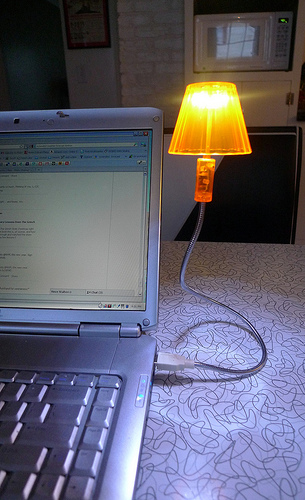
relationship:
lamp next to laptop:
[156, 81, 266, 378] [1, 105, 165, 498]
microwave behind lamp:
[194, 12, 292, 74] [156, 81, 266, 378]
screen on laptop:
[1, 129, 154, 310] [1, 105, 165, 498]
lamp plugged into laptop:
[156, 81, 266, 378] [1, 105, 165, 498]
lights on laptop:
[137, 375, 154, 409] [1, 105, 165, 498]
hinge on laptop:
[77, 322, 122, 340] [1, 105, 165, 498]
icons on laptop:
[2, 131, 153, 310] [1, 105, 165, 498]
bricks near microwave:
[117, 1, 186, 128] [194, 12, 292, 74]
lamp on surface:
[156, 81, 266, 378] [131, 239, 304, 499]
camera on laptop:
[14, 118, 21, 125] [1, 105, 165, 498]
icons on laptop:
[96, 302, 131, 311] [1, 105, 165, 498]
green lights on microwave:
[279, 18, 289, 24] [194, 12, 292, 74]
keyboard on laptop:
[1, 368, 124, 499] [1, 105, 165, 498]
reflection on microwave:
[193, 14, 272, 67] [194, 12, 292, 74]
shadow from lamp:
[172, 317, 259, 351] [156, 81, 266, 378]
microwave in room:
[194, 12, 292, 74] [0, 0, 304, 500]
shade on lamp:
[167, 81, 251, 156] [156, 81, 266, 378]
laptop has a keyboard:
[1, 105, 165, 498] [1, 368, 124, 499]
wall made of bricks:
[117, 1, 185, 129] [117, 1, 186, 128]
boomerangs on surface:
[133, 241, 305, 500] [131, 239, 304, 499]